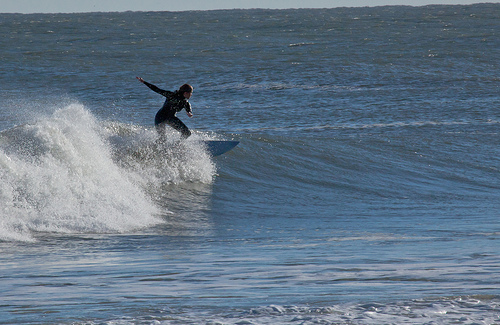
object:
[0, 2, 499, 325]
water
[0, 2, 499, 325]
ripples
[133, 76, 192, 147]
woman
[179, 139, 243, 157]
surfboard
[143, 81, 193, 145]
wetsuit